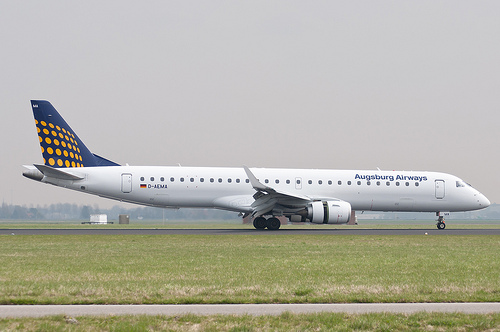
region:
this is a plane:
[6, 97, 498, 234]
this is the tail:
[24, 93, 89, 163]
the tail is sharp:
[24, 95, 84, 158]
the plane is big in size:
[8, 94, 493, 212]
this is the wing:
[238, 171, 293, 206]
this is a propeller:
[305, 194, 355, 224]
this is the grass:
[288, 239, 384, 293]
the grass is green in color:
[312, 235, 398, 280]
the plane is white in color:
[194, 178, 220, 196]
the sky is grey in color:
[140, 13, 451, 156]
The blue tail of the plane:
[25, 93, 120, 166]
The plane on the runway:
[18, 87, 493, 234]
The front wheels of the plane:
[428, 210, 455, 230]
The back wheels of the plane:
[246, 205, 288, 237]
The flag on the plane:
[136, 177, 150, 192]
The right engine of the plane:
[294, 189, 359, 231]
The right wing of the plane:
[217, 160, 315, 223]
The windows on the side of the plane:
[137, 172, 424, 189]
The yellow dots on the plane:
[33, 117, 88, 167]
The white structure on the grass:
[87, 209, 112, 225]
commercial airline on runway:
[18, 94, 498, 228]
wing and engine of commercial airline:
[212, 189, 359, 222]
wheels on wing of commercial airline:
[247, 215, 283, 229]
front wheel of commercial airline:
[433, 211, 446, 229]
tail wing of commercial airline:
[30, 98, 123, 166]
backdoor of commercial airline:
[120, 173, 131, 193]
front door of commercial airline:
[434, 179, 444, 199]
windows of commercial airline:
[137, 174, 424, 183]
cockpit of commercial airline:
[452, 181, 467, 188]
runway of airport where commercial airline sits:
[2, 226, 499, 233]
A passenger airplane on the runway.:
[15, 78, 497, 241]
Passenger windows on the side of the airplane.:
[130, 165, 432, 192]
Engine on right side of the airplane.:
[303, 191, 355, 226]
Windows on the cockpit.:
[451, 170, 476, 197]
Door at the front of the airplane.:
[428, 173, 448, 204]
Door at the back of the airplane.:
[120, 165, 135, 200]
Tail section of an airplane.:
[23, 88, 119, 173]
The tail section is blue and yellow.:
[24, 90, 119, 167]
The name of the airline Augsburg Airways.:
[350, 169, 430, 181]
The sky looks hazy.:
[18, 13, 478, 167]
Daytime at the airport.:
[0, 2, 495, 327]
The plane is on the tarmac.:
[1, 85, 496, 233]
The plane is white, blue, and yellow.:
[10, 91, 490, 229]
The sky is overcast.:
[3, 2, 498, 69]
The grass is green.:
[0, 243, 495, 273]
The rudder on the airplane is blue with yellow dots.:
[22, 91, 114, 163]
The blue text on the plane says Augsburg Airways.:
[351, 167, 432, 180]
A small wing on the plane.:
[26, 157, 86, 182]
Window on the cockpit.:
[452, 172, 464, 194]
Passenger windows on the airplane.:
[277, 175, 424, 192]